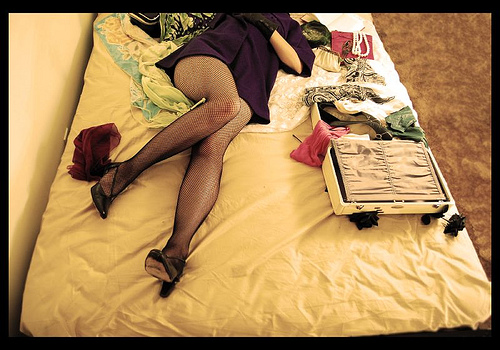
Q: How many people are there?
A: One.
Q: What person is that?
A: Woman.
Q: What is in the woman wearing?
A: Nylons.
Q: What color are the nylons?
A: Black.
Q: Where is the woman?
A: In bed.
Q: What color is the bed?
A: Cream.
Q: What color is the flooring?
A: Brown.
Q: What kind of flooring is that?
A: Carpet.